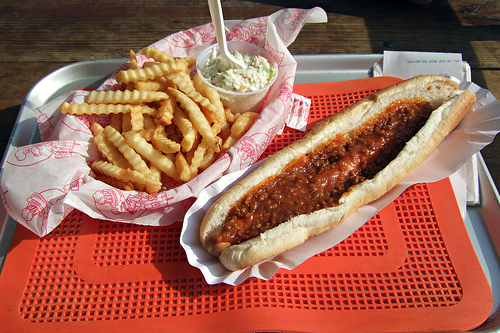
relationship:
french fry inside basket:
[60, 47, 259, 195] [56, 19, 296, 214]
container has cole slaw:
[195, 38, 277, 112] [203, 52, 275, 92]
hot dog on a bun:
[212, 97, 430, 250] [196, 73, 477, 270]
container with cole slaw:
[195, 38, 277, 112] [201, 49, 275, 92]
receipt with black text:
[381, 51, 463, 83] [402, 56, 462, 65]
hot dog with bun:
[212, 97, 430, 250] [196, 73, 477, 270]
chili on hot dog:
[214, 95, 431, 243] [195, 79, 472, 276]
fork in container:
[205, 0, 245, 72] [195, 38, 277, 112]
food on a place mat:
[59, 61, 442, 256] [0, 77, 494, 333]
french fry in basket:
[60, 47, 259, 195] [4, 3, 341, 246]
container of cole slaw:
[195, 38, 277, 112] [201, 49, 275, 92]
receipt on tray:
[377, 42, 487, 210] [35, 33, 497, 310]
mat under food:
[2, 67, 492, 325] [7, 1, 497, 286]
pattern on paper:
[166, 20, 215, 47] [1, 6, 327, 236]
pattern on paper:
[7, 141, 79, 165] [1, 6, 327, 236]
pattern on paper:
[237, 125, 282, 167] [1, 6, 327, 236]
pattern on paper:
[91, 187, 175, 220] [1, 6, 327, 236]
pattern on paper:
[22, 177, 87, 233] [1, 6, 327, 236]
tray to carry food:
[0, 51, 498, 329] [53, 13, 464, 282]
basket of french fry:
[56, 19, 296, 214] [60, 47, 259, 195]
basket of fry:
[56, 19, 296, 214] [86, 89, 163, 101]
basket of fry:
[56, 19, 296, 214] [61, 101, 153, 113]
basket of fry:
[56, 19, 296, 214] [150, 131, 182, 153]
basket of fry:
[56, 19, 296, 214] [106, 128, 148, 171]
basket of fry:
[56, 19, 296, 214] [90, 159, 133, 179]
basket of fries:
[20, 32, 328, 239] [63, 54, 251, 194]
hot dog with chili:
[195, 79, 472, 276] [228, 147, 343, 242]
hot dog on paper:
[212, 97, 430, 250] [30, 39, 123, 228]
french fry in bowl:
[57, 100, 132, 115] [55, 50, 303, 220]